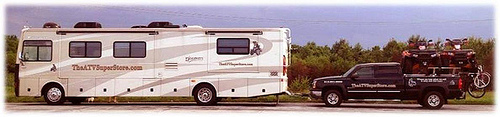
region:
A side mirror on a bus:
[23, 52, 28, 61]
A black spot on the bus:
[26, 86, 30, 93]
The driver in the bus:
[23, 50, 29, 60]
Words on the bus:
[73, 63, 141, 70]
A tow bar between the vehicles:
[288, 93, 308, 97]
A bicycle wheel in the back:
[473, 71, 488, 88]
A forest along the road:
[305, 53, 348, 64]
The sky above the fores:
[355, 28, 405, 37]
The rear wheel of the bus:
[195, 85, 212, 102]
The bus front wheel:
[43, 84, 63, 104]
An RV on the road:
[19, 22, 284, 104]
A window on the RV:
[216, 39, 248, 54]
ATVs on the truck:
[405, 38, 477, 66]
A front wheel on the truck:
[323, 90, 340, 105]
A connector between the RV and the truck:
[283, 86, 309, 98]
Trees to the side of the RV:
[298, 48, 336, 63]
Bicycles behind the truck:
[469, 58, 488, 93]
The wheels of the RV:
[38, 80, 218, 102]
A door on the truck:
[352, 74, 375, 94]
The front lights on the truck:
[310, 78, 317, 88]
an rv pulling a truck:
[12, 6, 432, 114]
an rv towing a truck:
[14, 18, 434, 115]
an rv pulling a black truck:
[25, 18, 490, 110]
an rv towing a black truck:
[14, 11, 486, 115]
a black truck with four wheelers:
[339, 31, 498, 97]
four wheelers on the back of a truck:
[314, 26, 479, 110]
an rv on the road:
[10, 9, 294, 111]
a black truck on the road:
[307, 19, 494, 115]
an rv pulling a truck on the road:
[12, 5, 457, 100]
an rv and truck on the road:
[11, 8, 498, 103]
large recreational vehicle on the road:
[11, 21, 298, 101]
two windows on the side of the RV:
[62, 36, 147, 64]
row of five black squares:
[69, 77, 184, 98]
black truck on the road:
[309, 41, 469, 115]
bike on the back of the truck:
[462, 60, 494, 101]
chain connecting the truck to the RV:
[283, 81, 317, 101]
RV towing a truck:
[12, 16, 491, 108]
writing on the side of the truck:
[347, 80, 402, 94]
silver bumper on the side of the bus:
[311, 88, 321, 98]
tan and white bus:
[14, 17, 297, 102]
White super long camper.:
[17, 18, 293, 107]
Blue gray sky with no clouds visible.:
[11, 7, 498, 22]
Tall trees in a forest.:
[297, 35, 387, 58]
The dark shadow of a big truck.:
[308, 99, 463, 111]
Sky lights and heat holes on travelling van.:
[70, 19, 185, 30]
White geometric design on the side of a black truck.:
[347, 82, 414, 96]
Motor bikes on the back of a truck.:
[399, 34, 493, 96]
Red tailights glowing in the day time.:
[280, 50, 295, 82]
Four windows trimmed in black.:
[21, 33, 262, 63]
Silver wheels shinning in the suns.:
[472, 66, 494, 89]